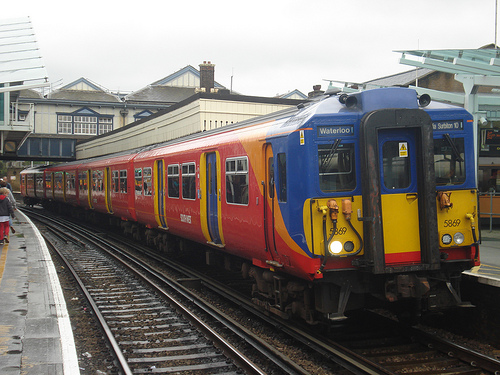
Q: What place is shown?
A: It is a station.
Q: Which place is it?
A: It is a station.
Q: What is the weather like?
A: It is cloudy.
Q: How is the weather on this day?
A: It is cloudy.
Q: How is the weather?
A: It is cloudy.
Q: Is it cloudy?
A: Yes, it is cloudy.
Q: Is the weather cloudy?
A: Yes, it is cloudy.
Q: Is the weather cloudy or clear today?
A: It is cloudy.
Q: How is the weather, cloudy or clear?
A: It is cloudy.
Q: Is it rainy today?
A: No, it is cloudy.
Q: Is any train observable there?
A: Yes, there is a train.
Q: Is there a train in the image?
A: Yes, there is a train.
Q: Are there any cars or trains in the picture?
A: Yes, there is a train.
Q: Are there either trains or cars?
A: Yes, there is a train.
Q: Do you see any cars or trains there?
A: Yes, there is a train.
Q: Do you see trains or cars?
A: Yes, there is a train.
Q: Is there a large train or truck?
A: Yes, there is a large train.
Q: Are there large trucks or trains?
A: Yes, there is a large train.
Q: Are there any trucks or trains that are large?
A: Yes, the train is large.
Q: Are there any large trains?
A: Yes, there is a large train.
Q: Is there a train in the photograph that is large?
A: Yes, there is a train that is large.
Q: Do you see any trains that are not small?
A: Yes, there is a large train.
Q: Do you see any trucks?
A: No, there are no trucks.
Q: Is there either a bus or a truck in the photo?
A: No, there are no trucks or buses.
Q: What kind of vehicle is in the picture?
A: The vehicle is a train.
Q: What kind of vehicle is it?
A: The vehicle is a train.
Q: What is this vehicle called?
A: This is a train.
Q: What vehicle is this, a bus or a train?
A: This is a train.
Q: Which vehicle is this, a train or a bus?
A: This is a train.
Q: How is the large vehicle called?
A: The vehicle is a train.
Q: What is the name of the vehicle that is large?
A: The vehicle is a train.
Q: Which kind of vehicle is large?
A: The vehicle is a train.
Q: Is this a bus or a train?
A: This is a train.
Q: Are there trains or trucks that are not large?
A: No, there is a train but it is large.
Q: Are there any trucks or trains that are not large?
A: No, there is a train but it is large.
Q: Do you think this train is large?
A: Yes, the train is large.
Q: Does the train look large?
A: Yes, the train is large.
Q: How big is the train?
A: The train is large.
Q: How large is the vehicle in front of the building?
A: The train is large.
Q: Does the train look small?
A: No, the train is large.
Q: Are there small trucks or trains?
A: No, there is a train but it is large.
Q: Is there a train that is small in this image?
A: No, there is a train but it is large.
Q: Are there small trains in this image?
A: No, there is a train but it is large.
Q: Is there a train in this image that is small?
A: No, there is a train but it is large.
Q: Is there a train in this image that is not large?
A: No, there is a train but it is large.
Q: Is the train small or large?
A: The train is large.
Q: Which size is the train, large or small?
A: The train is large.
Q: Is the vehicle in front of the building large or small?
A: The train is large.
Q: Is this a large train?
A: Yes, this is a large train.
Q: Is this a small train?
A: No, this is a large train.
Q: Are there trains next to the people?
A: Yes, there is a train next to the people.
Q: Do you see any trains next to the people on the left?
A: Yes, there is a train next to the people.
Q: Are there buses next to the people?
A: No, there is a train next to the people.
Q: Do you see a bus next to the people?
A: No, there is a train next to the people.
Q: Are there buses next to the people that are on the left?
A: No, there is a train next to the people.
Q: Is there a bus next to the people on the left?
A: No, there is a train next to the people.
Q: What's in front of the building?
A: The train is in front of the building.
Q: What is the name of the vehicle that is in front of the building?
A: The vehicle is a train.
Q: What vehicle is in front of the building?
A: The vehicle is a train.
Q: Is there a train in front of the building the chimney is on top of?
A: Yes, there is a train in front of the building.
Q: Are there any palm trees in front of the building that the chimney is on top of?
A: No, there is a train in front of the building.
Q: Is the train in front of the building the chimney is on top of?
A: Yes, the train is in front of the building.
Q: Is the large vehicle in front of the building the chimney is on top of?
A: Yes, the train is in front of the building.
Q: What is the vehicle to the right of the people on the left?
A: The vehicle is a train.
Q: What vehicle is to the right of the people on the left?
A: The vehicle is a train.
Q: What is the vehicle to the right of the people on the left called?
A: The vehicle is a train.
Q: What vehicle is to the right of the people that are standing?
A: The vehicle is a train.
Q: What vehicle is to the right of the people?
A: The vehicle is a train.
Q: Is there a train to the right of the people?
A: Yes, there is a train to the right of the people.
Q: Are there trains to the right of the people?
A: Yes, there is a train to the right of the people.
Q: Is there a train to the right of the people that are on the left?
A: Yes, there is a train to the right of the people.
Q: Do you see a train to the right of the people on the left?
A: Yes, there is a train to the right of the people.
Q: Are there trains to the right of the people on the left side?
A: Yes, there is a train to the right of the people.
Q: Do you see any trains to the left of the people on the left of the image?
A: No, the train is to the right of the people.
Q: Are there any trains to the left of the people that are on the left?
A: No, the train is to the right of the people.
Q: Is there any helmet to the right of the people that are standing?
A: No, there is a train to the right of the people.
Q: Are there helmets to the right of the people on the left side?
A: No, there is a train to the right of the people.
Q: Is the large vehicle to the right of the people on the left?
A: Yes, the train is to the right of the people.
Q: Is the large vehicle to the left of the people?
A: No, the train is to the right of the people.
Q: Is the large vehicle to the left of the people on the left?
A: No, the train is to the right of the people.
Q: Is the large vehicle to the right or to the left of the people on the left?
A: The train is to the right of the people.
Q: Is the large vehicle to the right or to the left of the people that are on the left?
A: The train is to the right of the people.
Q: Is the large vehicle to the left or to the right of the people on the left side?
A: The train is to the right of the people.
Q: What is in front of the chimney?
A: The train is in front of the chimney.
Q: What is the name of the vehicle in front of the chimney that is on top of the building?
A: The vehicle is a train.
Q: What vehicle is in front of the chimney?
A: The vehicle is a train.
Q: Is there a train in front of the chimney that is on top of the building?
A: Yes, there is a train in front of the chimney.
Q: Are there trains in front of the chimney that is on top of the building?
A: Yes, there is a train in front of the chimney.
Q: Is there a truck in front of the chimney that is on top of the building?
A: No, there is a train in front of the chimney.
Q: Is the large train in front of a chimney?
A: Yes, the train is in front of a chimney.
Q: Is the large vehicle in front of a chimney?
A: Yes, the train is in front of a chimney.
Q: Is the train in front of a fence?
A: No, the train is in front of a chimney.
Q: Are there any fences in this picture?
A: No, there are no fences.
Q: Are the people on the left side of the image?
A: Yes, the people are on the left of the image.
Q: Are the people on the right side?
A: No, the people are on the left of the image.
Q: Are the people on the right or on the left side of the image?
A: The people are on the left of the image.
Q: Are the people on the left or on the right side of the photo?
A: The people are on the left of the image.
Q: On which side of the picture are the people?
A: The people are on the left of the image.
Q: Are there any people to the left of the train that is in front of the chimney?
A: Yes, there are people to the left of the train.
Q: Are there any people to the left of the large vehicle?
A: Yes, there are people to the left of the train.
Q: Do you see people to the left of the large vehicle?
A: Yes, there are people to the left of the train.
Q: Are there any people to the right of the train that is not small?
A: No, the people are to the left of the train.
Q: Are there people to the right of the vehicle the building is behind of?
A: No, the people are to the left of the train.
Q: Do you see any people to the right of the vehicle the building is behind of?
A: No, the people are to the left of the train.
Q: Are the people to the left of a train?
A: Yes, the people are to the left of a train.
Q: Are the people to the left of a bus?
A: No, the people are to the left of a train.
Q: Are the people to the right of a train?
A: No, the people are to the left of a train.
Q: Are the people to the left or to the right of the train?
A: The people are to the left of the train.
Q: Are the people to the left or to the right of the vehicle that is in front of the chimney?
A: The people are to the left of the train.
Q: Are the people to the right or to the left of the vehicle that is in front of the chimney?
A: The people are to the left of the train.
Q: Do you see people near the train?
A: Yes, there are people near the train.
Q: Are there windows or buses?
A: Yes, there are windows.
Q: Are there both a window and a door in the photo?
A: Yes, there are both a window and a door.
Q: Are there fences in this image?
A: No, there are no fences.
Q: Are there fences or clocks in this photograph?
A: No, there are no fences or clocks.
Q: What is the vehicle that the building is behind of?
A: The vehicle is a train.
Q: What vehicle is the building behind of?
A: The building is behind the train.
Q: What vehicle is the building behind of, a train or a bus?
A: The building is behind a train.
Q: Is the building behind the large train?
A: Yes, the building is behind the train.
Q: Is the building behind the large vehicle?
A: Yes, the building is behind the train.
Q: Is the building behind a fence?
A: No, the building is behind the train.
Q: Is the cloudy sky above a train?
A: Yes, the sky is above a train.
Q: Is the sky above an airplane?
A: No, the sky is above a train.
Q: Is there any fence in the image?
A: No, there are no fences.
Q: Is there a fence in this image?
A: No, there are no fences.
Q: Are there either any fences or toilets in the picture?
A: No, there are no fences or toilets.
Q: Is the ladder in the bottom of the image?
A: Yes, the ladder is in the bottom of the image.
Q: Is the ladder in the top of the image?
A: No, the ladder is in the bottom of the image.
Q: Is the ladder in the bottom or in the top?
A: The ladder is in the bottom of the image.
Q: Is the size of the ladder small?
A: Yes, the ladder is small.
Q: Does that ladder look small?
A: Yes, the ladder is small.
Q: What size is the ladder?
A: The ladder is small.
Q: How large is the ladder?
A: The ladder is small.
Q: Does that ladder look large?
A: No, the ladder is small.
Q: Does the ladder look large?
A: No, the ladder is small.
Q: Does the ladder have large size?
A: No, the ladder is small.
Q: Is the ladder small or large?
A: The ladder is small.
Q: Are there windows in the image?
A: Yes, there is a window.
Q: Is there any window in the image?
A: Yes, there is a window.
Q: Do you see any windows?
A: Yes, there is a window.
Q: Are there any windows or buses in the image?
A: Yes, there is a window.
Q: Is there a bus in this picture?
A: No, there are no buses.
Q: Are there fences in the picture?
A: No, there are no fences.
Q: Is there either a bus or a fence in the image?
A: No, there are no fences or buses.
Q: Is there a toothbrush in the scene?
A: No, there are no toothbrushes.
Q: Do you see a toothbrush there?
A: No, there are no toothbrushes.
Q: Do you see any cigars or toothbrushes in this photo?
A: No, there are no toothbrushes or cigars.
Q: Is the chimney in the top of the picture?
A: Yes, the chimney is in the top of the image.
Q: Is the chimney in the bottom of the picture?
A: No, the chimney is in the top of the image.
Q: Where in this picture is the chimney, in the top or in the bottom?
A: The chimney is in the top of the image.